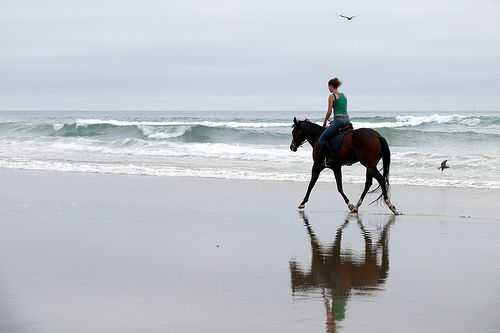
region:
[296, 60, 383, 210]
A girl on a horse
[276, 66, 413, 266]
Girl riding a horse on the shoreline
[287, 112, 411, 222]
Horse is near the ocean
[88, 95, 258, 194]
Waves from the sea coming to the shore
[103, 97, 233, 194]
Large waves coming to shore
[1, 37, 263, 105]
It is a very cloudy day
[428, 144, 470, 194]
A bird flying near the water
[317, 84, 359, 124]
The girl is wearing a green shirt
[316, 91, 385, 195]
Girl is riding a brown horse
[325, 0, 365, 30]
A bird flying high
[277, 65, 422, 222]
Horse walking along the shore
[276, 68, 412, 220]
Woman riding a horse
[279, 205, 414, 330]
Reflection in the sand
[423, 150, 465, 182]
One bird flying near the shore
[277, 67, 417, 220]
The horse is brown and black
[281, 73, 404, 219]
Woman wearing green tank top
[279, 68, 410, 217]
Woman wearing pants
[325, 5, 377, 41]
Bird flying above the shore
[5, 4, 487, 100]
Grey and cloudy sky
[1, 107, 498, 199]
Waves along the shore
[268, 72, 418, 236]
a woman on a horse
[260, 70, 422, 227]
a woman on a horse at the beach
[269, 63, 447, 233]
a woman riding on a beach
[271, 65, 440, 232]
a woman riding on a horse on the beach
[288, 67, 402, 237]
A woman riding a horse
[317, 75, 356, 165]
A woman sitting in a saddle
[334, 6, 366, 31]
A bird flying in the air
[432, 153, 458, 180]
A bird flying near the water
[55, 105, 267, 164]
A wave in the ocean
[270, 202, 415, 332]
Reflection of a woman and a horse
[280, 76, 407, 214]
woman riding a horse on the beach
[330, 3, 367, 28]
seagull flying in the sky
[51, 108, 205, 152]
waves just about to break on shore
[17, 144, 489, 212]
ocean water beginning to receed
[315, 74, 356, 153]
woman in green tank top sitting on a horse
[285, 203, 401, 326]
shadow of horse and rider on wet sand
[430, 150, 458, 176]
a bird swooping down to the ocean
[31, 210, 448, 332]
wet, untouched sand of a beach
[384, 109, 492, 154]
a second wave approaching the shore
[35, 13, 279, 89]
an overcast sky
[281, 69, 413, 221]
woman riding a horse in front of ocean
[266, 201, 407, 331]
shadow of a woman and a horse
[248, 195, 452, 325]
shadow cast on wet sand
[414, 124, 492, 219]
a bird flying close to the sand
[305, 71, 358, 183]
woman wears a green top tank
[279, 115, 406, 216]
horse is black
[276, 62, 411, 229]
woman riding to the left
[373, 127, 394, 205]
tail of horse is long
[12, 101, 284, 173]
waves in the ocean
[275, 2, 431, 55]
bird flies in an overcast sky